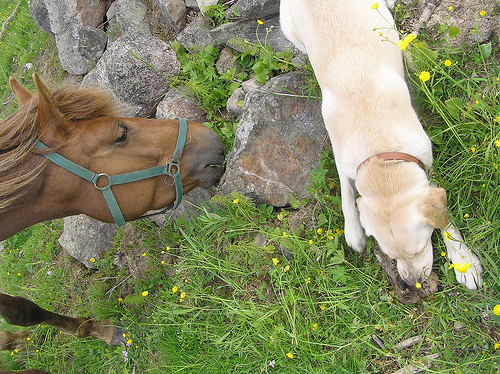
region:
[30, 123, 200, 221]
The green harness around the horse's face.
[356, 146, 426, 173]
The brown collar around the dog's neck.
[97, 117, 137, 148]
The eye of the horse.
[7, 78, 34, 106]
The left ear of the horse.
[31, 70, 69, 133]
The right ear of the horse.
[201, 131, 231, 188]
The nose and mouth of the horse.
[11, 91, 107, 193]
The brown hair of the horse's mane.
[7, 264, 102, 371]
The legs of the horse.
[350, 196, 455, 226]
The ears of the dog.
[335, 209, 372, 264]
The dog's left paw.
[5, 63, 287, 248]
brown horse eat grass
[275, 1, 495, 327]
yellow dog with leather collar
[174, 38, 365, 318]
rocks in a pile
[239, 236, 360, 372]
small yellow flowers blooming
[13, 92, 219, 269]
green halter on horse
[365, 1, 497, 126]
small yellow flowers blooming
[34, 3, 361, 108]
large rocks piled in pasture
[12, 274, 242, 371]
horses hoove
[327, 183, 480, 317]
brown leather dog collardog chewing on something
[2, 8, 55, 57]
grass with small bloomng yellow flowers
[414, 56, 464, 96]
yellow petals on flower stalk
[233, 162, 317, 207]
tiny white lines on stone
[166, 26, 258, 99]
green bush peeking out of the stones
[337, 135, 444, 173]
brown collar on the dog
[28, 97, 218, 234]
blue rein around horse's face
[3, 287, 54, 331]
fat calf on the brown horse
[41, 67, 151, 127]
bushy mane on horse's face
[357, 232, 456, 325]
dog's face in the dirt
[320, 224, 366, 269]
dog's white foot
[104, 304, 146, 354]
black hoof on horse's foot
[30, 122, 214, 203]
horse has blue bridle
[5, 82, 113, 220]
horse has brown mane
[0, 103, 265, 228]
horse is coffee-colored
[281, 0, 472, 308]
dog is white and tan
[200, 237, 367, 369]
grass is green and thick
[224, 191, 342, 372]
yellow flowering weeds in grass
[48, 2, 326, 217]
horse has nose in rocks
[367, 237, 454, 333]
dog is digging in ground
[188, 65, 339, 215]
rocks between horse and dog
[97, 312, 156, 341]
horse has dark brown hoof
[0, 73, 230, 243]
Horse's head looking at dog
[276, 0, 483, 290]
White dog sniffing ground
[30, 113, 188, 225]
Green harness on horse's head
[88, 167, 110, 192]
Metal circle on the right of harness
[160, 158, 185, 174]
Metal round circle of harness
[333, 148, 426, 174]
Tan dog collar on dog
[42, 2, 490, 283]
Rock formation in back of horse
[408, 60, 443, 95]
Yellow flower growing in grass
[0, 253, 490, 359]
Grass with yellow flowers growing in it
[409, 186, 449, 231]
White dog's left ear